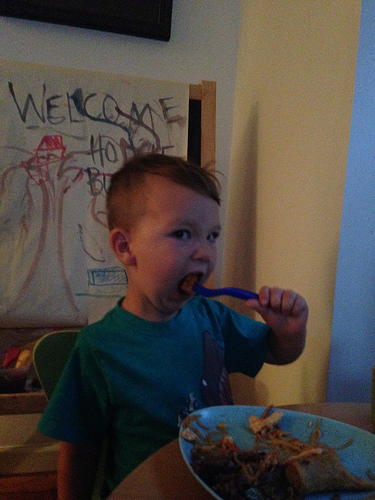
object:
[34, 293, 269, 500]
shirt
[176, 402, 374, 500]
bowl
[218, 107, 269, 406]
shadow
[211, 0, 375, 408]
wall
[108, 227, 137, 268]
ear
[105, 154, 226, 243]
hair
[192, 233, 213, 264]
nose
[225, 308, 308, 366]
arm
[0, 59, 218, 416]
board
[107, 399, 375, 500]
table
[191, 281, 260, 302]
spoon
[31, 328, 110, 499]
chair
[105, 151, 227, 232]
hair cut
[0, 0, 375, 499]
house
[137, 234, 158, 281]
skin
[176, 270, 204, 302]
mouth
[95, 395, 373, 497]
wood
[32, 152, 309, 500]
baby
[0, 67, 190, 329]
art work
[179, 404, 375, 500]
noodles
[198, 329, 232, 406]
shark